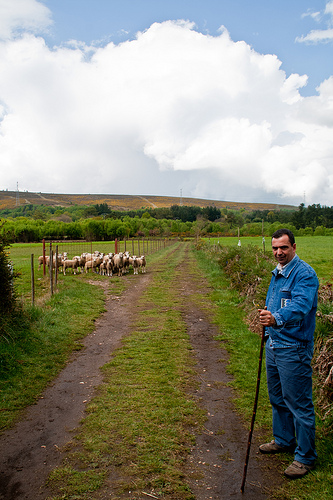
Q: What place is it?
A: It is a field.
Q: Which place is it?
A: It is a field.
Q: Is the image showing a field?
A: Yes, it is showing a field.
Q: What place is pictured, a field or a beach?
A: It is a field.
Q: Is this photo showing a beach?
A: No, the picture is showing a field.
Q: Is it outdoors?
A: Yes, it is outdoors.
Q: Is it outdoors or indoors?
A: It is outdoors.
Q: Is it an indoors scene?
A: No, it is outdoors.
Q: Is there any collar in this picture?
A: Yes, there is a collar.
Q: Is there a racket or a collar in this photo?
A: Yes, there is a collar.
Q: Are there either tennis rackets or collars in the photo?
A: Yes, there is a collar.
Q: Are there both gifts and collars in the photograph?
A: No, there is a collar but no gifts.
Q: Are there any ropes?
A: No, there are no ropes.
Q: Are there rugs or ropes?
A: No, there are no ropes or rugs.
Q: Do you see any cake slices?
A: No, there are no cake slices.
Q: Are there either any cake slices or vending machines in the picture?
A: No, there are no cake slices or vending machines.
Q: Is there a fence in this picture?
A: Yes, there is a fence.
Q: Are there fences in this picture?
A: Yes, there is a fence.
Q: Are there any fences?
A: Yes, there is a fence.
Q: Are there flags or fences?
A: Yes, there is a fence.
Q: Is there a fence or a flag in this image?
A: Yes, there is a fence.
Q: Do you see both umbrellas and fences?
A: No, there is a fence but no umbrellas.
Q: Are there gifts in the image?
A: No, there are no gifts.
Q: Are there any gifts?
A: No, there are no gifts.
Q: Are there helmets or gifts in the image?
A: No, there are no gifts or helmets.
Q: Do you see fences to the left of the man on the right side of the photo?
A: Yes, there is a fence to the left of the man.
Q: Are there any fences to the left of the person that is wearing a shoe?
A: Yes, there is a fence to the left of the man.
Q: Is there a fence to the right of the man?
A: No, the fence is to the left of the man.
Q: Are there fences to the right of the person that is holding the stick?
A: No, the fence is to the left of the man.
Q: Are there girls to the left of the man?
A: No, there is a fence to the left of the man.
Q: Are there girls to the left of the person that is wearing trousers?
A: No, there is a fence to the left of the man.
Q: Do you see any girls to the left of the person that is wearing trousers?
A: No, there is a fence to the left of the man.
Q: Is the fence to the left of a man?
A: Yes, the fence is to the left of a man.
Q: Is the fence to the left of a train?
A: No, the fence is to the left of a man.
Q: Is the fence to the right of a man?
A: No, the fence is to the left of a man.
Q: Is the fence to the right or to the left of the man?
A: The fence is to the left of the man.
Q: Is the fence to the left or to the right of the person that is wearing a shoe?
A: The fence is to the left of the man.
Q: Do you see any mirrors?
A: No, there are no mirrors.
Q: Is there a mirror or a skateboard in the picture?
A: No, there are no mirrors or skateboards.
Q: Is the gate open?
A: Yes, the gate is open.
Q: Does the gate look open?
A: Yes, the gate is open.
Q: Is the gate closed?
A: No, the gate is open.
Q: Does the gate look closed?
A: No, the gate is open.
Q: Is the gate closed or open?
A: The gate is open.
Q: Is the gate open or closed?
A: The gate is open.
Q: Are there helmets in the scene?
A: No, there are no helmets.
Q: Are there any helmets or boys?
A: No, there are no helmets or boys.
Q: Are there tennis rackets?
A: No, there are no tennis rackets.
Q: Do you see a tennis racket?
A: No, there are no rackets.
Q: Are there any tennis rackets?
A: No, there are no tennis rackets.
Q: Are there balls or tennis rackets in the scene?
A: No, there are no tennis rackets or balls.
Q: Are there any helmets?
A: No, there are no helmets.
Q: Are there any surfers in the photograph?
A: No, there are no surfers.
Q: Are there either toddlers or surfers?
A: No, there are no surfers or toddlers.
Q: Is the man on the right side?
A: Yes, the man is on the right of the image.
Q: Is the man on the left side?
A: No, the man is on the right of the image.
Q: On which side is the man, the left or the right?
A: The man is on the right of the image.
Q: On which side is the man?
A: The man is on the right of the image.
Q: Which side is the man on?
A: The man is on the right of the image.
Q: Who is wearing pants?
A: The man is wearing pants.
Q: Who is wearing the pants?
A: The man is wearing pants.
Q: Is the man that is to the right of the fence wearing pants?
A: Yes, the man is wearing pants.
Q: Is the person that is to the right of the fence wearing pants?
A: Yes, the man is wearing pants.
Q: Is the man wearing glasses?
A: No, the man is wearing pants.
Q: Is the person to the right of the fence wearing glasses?
A: No, the man is wearing pants.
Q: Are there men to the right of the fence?
A: Yes, there is a man to the right of the fence.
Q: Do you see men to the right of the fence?
A: Yes, there is a man to the right of the fence.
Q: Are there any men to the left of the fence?
A: No, the man is to the right of the fence.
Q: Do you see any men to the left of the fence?
A: No, the man is to the right of the fence.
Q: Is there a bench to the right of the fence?
A: No, there is a man to the right of the fence.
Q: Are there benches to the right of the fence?
A: No, there is a man to the right of the fence.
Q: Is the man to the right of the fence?
A: Yes, the man is to the right of the fence.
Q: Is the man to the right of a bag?
A: No, the man is to the right of the fence.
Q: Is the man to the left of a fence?
A: No, the man is to the right of a fence.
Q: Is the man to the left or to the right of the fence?
A: The man is to the right of the fence.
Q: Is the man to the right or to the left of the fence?
A: The man is to the right of the fence.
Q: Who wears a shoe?
A: The man wears a shoe.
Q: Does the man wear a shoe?
A: Yes, the man wears a shoe.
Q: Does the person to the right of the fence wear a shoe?
A: Yes, the man wears a shoe.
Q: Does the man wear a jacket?
A: No, the man wears a shoe.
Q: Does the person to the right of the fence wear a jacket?
A: No, the man wears a shoe.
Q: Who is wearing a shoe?
A: The man is wearing a shoe.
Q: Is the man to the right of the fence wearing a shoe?
A: Yes, the man is wearing a shoe.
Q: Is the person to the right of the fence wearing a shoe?
A: Yes, the man is wearing a shoe.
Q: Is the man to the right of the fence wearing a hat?
A: No, the man is wearing a shoe.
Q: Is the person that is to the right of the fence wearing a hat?
A: No, the man is wearing a shoe.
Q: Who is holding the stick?
A: The man is holding the stick.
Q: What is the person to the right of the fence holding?
A: The man is holding the stick.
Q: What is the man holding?
A: The man is holding the stick.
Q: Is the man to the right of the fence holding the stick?
A: Yes, the man is holding the stick.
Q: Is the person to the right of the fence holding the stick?
A: Yes, the man is holding the stick.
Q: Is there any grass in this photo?
A: Yes, there is grass.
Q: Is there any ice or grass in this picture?
A: Yes, there is grass.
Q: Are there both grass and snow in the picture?
A: No, there is grass but no snow.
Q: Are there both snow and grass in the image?
A: No, there is grass but no snow.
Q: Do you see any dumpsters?
A: No, there are no dumpsters.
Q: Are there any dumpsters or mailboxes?
A: No, there are no dumpsters or mailboxes.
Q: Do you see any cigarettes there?
A: No, there are no cigarettes.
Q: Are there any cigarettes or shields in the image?
A: No, there are no cigarettes or shields.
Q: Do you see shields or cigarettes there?
A: No, there are no cigarettes or shields.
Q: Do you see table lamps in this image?
A: No, there are no table lamps.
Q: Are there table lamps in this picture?
A: No, there are no table lamps.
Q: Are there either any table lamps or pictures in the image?
A: No, there are no table lamps or pictures.